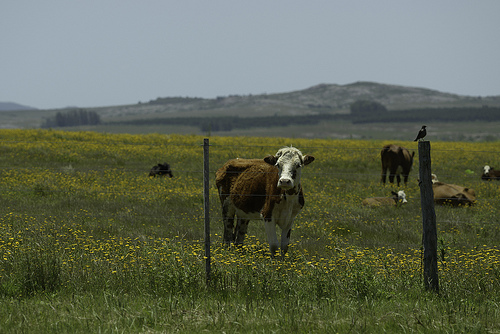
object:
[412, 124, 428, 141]
bird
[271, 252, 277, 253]
flowers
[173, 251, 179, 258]
flowers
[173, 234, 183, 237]
flowers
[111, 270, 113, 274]
flowers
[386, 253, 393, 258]
flowers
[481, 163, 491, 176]
face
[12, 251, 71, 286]
wild flowers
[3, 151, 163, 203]
wild flowers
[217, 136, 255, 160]
wild flowers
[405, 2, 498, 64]
sky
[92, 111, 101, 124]
tree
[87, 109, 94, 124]
tree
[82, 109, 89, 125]
tree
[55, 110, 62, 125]
tree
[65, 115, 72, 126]
tree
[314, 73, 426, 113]
hill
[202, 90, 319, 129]
hill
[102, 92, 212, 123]
hill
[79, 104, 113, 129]
meadow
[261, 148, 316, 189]
head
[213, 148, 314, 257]
cattle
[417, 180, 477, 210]
cattle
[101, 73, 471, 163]
mountains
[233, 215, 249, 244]
legs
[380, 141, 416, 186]
cattle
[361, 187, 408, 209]
cattle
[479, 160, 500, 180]
cattle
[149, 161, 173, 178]
cattle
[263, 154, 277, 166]
ear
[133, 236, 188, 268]
flowers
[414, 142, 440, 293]
fence post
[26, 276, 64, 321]
grass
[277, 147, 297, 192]
face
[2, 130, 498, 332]
field